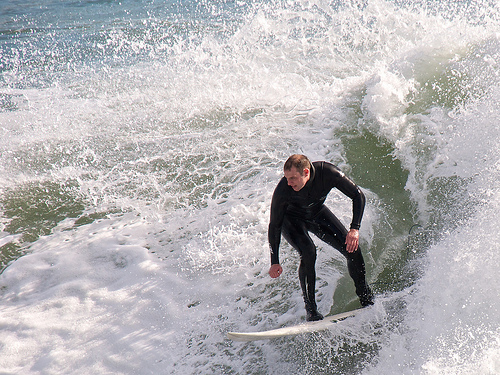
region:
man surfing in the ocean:
[256, 144, 393, 364]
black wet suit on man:
[269, 182, 360, 315]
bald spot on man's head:
[289, 149, 311, 160]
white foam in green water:
[68, 288, 168, 347]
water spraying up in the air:
[89, 39, 216, 114]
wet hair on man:
[287, 155, 307, 167]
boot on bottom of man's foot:
[302, 289, 337, 326]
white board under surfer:
[229, 301, 406, 345]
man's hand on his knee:
[343, 192, 368, 262]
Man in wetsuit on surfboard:
[217, 156, 389, 336]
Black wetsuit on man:
[269, 160, 369, 308]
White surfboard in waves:
[230, 307, 411, 337]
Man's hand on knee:
[344, 229, 359, 255]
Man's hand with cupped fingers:
[267, 266, 283, 276]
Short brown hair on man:
[283, 153, 310, 166]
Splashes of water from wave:
[0, 5, 192, 67]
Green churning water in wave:
[7, 180, 68, 242]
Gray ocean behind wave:
[3, 4, 178, 49]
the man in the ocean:
[205, 131, 405, 336]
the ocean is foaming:
[52, 184, 238, 341]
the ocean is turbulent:
[24, 21, 496, 223]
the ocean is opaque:
[14, 3, 473, 368]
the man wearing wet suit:
[257, 152, 406, 319]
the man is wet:
[254, 163, 391, 314]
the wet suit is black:
[241, 158, 411, 306]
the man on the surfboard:
[268, 154, 395, 310]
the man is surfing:
[256, 158, 386, 314]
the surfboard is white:
[212, 306, 405, 350]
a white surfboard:
[224, 303, 375, 340]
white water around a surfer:
[0, 0, 496, 372]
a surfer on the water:
[265, 151, 376, 319]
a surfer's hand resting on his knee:
[342, 228, 357, 254]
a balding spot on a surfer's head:
[285, 151, 306, 166]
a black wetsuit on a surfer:
[265, 165, 370, 320]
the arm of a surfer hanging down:
[265, 190, 280, 275]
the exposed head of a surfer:
[280, 150, 310, 192]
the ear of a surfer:
[301, 166, 314, 178]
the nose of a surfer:
[285, 177, 293, 187]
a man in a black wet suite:
[256, 148, 374, 327]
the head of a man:
[281, 153, 316, 195]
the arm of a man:
[263, 198, 288, 281]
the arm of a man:
[330, 161, 365, 256]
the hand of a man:
[265, 257, 286, 280]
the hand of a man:
[341, 224, 363, 257]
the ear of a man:
[301, 163, 311, 178]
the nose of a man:
[283, 176, 296, 188]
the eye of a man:
[288, 170, 302, 182]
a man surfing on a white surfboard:
[223, 148, 439, 342]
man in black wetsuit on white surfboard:
[229, 138, 395, 341]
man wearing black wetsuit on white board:
[266, 148, 382, 324]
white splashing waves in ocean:
[10, 6, 494, 368]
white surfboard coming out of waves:
[228, 280, 435, 340]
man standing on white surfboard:
[216, 144, 411, 339]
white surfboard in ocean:
[236, 285, 431, 340]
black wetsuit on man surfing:
[250, 157, 394, 328]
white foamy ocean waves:
[3, 11, 493, 363]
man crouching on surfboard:
[226, 154, 400, 342]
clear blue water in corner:
[3, 0, 249, 85]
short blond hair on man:
[277, 152, 317, 193]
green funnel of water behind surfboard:
[312, 93, 434, 310]